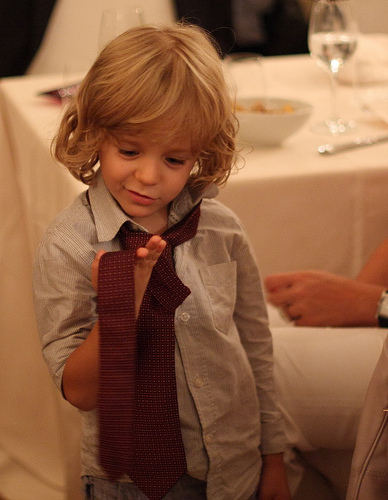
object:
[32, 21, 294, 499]
boy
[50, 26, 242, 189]
hair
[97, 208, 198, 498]
tie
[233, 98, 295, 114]
food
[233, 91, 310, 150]
bowl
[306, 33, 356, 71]
water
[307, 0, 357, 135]
glass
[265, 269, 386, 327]
hand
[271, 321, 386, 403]
lap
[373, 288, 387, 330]
watch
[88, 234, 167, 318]
hand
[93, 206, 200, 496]
dots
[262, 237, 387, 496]
person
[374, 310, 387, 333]
band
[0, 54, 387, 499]
table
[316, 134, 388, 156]
knife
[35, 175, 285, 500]
shirt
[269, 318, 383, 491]
pants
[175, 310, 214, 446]
buttons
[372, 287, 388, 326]
wrist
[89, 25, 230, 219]
head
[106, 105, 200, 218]
face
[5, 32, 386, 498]
table cloth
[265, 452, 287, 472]
wrist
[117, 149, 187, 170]
eyes